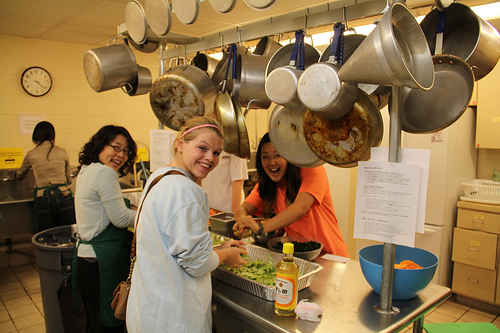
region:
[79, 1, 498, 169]
pots hanging from the rack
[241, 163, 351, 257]
orange shirt on the girl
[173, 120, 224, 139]
pink headband on the girl's head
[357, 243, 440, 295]
blue bowl on the counter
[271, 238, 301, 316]
bottle of oil with a yellow cap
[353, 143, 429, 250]
white papers hanging up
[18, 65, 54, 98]
white and black clock on the wall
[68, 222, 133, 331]
green apron on the woman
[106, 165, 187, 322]
brown purse on the woman's shoulder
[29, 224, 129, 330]
trashcan behind the girls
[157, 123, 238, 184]
the head of a woman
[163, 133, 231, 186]
the face of a woman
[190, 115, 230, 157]
the eye of a woman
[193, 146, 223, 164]
the nose of a woman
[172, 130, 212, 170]
the ear of a woman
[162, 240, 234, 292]
the elbow of a woman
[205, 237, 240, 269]
the wrist of a woman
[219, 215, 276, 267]
the hand of a woman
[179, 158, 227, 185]
the teeth of a woman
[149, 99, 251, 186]
the hair of a woman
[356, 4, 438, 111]
pan hanging on a rack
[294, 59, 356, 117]
pan hanging on a rack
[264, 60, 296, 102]
pan hanging on a rack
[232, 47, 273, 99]
pan hanging on a rack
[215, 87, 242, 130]
pan hanging on a rack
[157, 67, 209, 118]
pan hanging on a rack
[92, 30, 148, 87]
pan hanging on a rack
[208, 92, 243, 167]
pan hanging on a rack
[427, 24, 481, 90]
pan hanging on a rack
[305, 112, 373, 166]
pan hanging on a rack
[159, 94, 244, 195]
head of a person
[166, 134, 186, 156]
ear of a person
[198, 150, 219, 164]
nose of a person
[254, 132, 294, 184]
head of a person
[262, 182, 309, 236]
arm of a person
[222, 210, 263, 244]
hand of a person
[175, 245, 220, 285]
arm of a person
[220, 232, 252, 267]
hand of a person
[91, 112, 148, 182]
head of a person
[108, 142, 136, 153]
eye of a person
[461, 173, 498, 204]
A white dish strainer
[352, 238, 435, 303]
A large blue bowl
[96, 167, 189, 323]
A brown crossbody bag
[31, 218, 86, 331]
A dark grey trashcan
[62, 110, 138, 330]
A woman wearing a green apron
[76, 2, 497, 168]
Pots and pans hanging up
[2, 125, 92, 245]
A woman facing the sink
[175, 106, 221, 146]
A pink hairband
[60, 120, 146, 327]
A woman with black hair